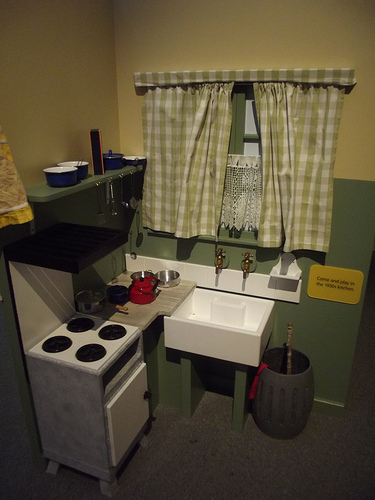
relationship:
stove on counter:
[23, 313, 154, 493] [99, 268, 277, 427]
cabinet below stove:
[106, 358, 151, 459] [6, 223, 154, 490]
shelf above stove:
[26, 160, 148, 215] [34, 313, 136, 365]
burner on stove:
[40, 335, 72, 352] [6, 223, 154, 490]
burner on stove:
[63, 317, 94, 332] [6, 223, 154, 490]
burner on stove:
[95, 324, 126, 339] [6, 223, 154, 490]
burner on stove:
[76, 342, 106, 363] [6, 223, 154, 490]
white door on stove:
[107, 362, 148, 467] [23, 313, 154, 493]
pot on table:
[125, 269, 159, 311] [78, 263, 196, 422]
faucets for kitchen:
[211, 246, 254, 277] [3, 2, 373, 495]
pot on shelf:
[40, 163, 79, 189] [17, 157, 143, 230]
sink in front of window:
[160, 285, 277, 369] [226, 83, 266, 155]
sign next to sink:
[305, 262, 364, 304] [164, 282, 280, 363]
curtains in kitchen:
[124, 60, 358, 264] [3, 2, 373, 495]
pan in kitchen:
[72, 286, 127, 318] [4, 55, 373, 492]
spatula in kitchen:
[89, 173, 112, 236] [4, 55, 373, 492]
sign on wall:
[305, 262, 364, 304] [114, 0, 371, 420]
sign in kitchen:
[305, 262, 364, 304] [0, 0, 375, 498]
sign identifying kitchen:
[304, 262, 363, 304] [16, 44, 373, 410]